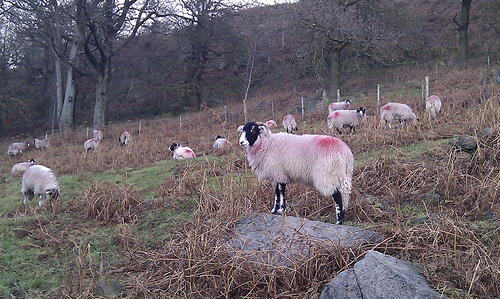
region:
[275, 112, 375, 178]
sheep have red markings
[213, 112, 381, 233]
sheep has black face and legs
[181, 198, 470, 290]
sheep standing on large rock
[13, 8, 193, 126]
several trees without leaves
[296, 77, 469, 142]
sheep on a hill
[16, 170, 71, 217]
sheep eating grass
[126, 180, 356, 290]
dry grass around large rock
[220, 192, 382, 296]
rocks are angular and grey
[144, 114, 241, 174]
some sheep sitting on the hill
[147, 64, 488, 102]
fence behind the sheep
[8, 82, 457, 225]
sheep in a field.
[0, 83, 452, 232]
black and white sheep.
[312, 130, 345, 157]
red paint on sheep.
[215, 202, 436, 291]
rocks on the ground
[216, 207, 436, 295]
the rocks are grey.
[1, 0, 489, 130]
trees in the background.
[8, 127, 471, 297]
the grass is green.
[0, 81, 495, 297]
the grass is dry.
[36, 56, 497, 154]
fence in the background.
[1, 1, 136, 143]
the tree is brown.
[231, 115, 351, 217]
a black and white standing sheep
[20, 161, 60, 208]
a black and white standing sheep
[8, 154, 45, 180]
a black and white standing sheep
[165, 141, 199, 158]
a black and white standing sheep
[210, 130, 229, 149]
a black and white standing sheep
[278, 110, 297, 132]
a black and white standing sheep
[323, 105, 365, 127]
a black and white standing sheep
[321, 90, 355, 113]
a black and white standing sheep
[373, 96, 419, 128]
a black and white grazing sheep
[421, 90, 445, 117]
a black and white grazing sheep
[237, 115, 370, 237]
sheep on a rock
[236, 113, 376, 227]
sheep with red spot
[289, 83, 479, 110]
fence in the field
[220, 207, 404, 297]
large rocks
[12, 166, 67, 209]
sheep eating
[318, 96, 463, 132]
sheep with red spots on their backs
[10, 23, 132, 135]
group of tall trees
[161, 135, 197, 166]
a sheep laying in a field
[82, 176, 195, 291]
clumps of dead grasses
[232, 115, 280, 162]
sheep with black face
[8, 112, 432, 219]
herding sheep with red spots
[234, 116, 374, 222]
shaggy sheep with red spot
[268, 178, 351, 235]
black legs on white sheep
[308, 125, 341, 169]
red paint spot on a sheep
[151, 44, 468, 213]
sheep grazing on a hillside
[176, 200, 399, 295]
straw in the pasture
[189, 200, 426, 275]
large boulders in the pasture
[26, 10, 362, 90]
trees with no leaves in the pasture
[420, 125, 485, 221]
pile of rocks in the pasture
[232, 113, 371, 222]
sheep with red behind on a rock